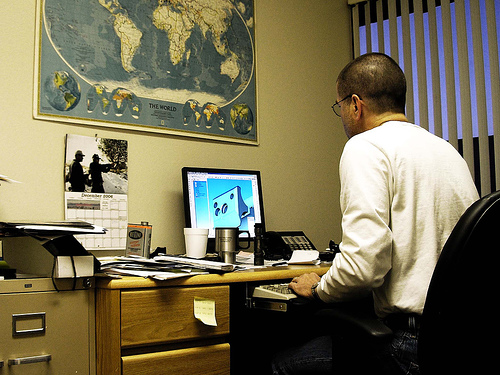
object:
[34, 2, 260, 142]
world map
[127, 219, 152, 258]
can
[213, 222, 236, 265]
cup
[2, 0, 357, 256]
wall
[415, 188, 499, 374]
chair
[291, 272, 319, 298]
hand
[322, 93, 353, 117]
glasses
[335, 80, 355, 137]
face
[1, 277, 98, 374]
cabinet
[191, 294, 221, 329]
yellow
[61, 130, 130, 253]
calendar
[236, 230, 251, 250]
handle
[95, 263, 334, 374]
desk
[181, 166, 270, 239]
computer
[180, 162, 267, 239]
monitor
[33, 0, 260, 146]
map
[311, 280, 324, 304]
watch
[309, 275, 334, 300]
wrist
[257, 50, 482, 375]
man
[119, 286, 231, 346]
drawer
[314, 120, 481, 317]
shirt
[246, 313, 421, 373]
jeans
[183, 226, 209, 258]
cup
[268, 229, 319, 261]
phone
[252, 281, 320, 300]
keyboard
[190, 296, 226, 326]
sticky note